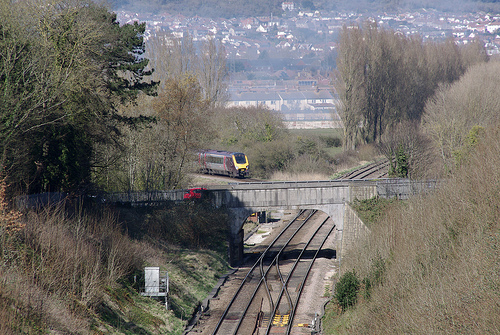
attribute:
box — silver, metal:
[143, 262, 162, 293]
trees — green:
[0, 6, 158, 213]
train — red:
[174, 186, 204, 202]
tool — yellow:
[271, 312, 291, 326]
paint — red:
[184, 187, 204, 199]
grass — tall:
[327, 167, 499, 332]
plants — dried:
[390, 246, 442, 320]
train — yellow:
[219, 151, 262, 179]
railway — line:
[191, 151, 409, 333]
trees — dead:
[320, 3, 487, 194]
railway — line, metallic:
[208, 245, 335, 320]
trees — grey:
[343, 50, 470, 292]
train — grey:
[159, 122, 296, 190]